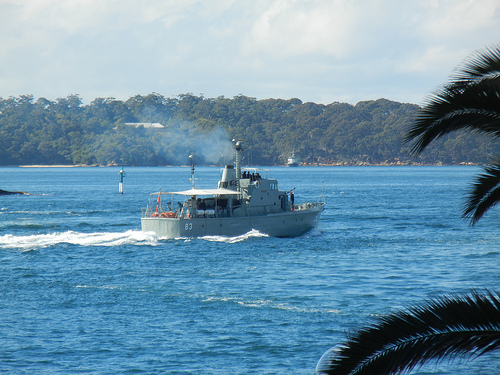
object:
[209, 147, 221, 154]
smoke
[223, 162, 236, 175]
stack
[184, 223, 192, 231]
83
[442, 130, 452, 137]
leaves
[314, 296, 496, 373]
tree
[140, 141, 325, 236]
boat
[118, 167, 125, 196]
buoy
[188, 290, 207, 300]
water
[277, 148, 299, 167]
house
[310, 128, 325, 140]
trees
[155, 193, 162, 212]
flag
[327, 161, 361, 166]
shoreline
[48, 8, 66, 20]
clouds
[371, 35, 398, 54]
sky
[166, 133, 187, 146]
steam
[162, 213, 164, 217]
life jackets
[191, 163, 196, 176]
pole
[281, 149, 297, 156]
roof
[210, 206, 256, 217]
bridge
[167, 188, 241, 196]
overhang